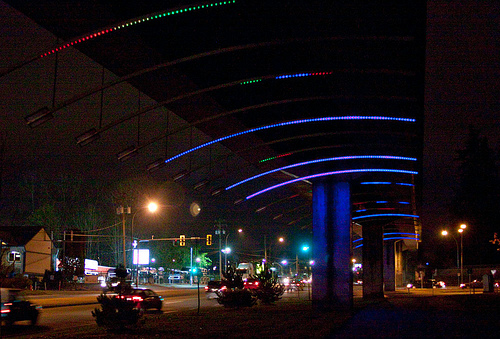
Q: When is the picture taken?
A: Night time.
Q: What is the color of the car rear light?
A: Red.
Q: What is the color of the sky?
A: Black.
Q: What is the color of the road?
A: Grey.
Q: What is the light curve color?
A: Blue.